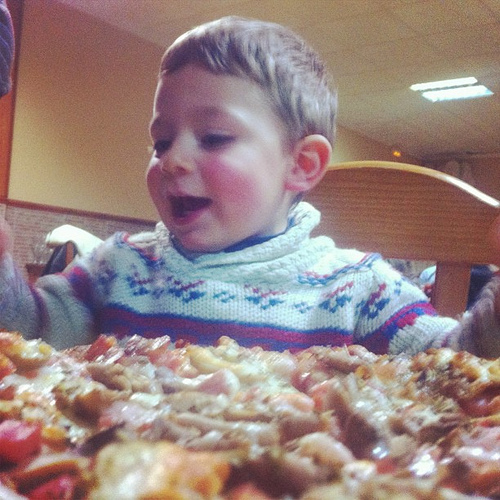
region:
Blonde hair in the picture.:
[162, 24, 352, 101]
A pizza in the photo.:
[143, 353, 480, 488]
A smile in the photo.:
[162, 180, 223, 230]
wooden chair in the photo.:
[322, 163, 472, 243]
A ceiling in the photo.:
[341, 4, 442, 54]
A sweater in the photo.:
[36, 232, 452, 347]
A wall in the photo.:
[25, 49, 116, 179]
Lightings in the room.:
[402, 70, 495, 109]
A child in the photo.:
[0, 17, 499, 357]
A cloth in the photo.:
[39, 222, 94, 261]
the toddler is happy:
[99, 57, 248, 241]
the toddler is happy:
[162, 152, 300, 262]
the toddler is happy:
[131, 97, 301, 302]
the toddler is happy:
[102, 97, 419, 356]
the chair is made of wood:
[350, 140, 420, 247]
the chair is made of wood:
[379, 158, 460, 300]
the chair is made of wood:
[364, 150, 487, 350]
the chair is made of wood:
[420, 151, 497, 313]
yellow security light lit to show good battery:
[389, 144, 403, 158]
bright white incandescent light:
[407, 75, 493, 103]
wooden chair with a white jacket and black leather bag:
[40, 223, 104, 279]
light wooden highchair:
[303, 159, 498, 317]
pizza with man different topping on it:
[0, 332, 499, 499]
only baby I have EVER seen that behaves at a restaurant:
[144, 14, 339, 251]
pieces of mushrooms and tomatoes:
[0, 417, 91, 498]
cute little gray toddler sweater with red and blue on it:
[0, 202, 499, 359]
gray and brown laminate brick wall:
[0, 196, 156, 286]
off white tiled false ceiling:
[56, 0, 498, 164]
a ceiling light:
[422, 83, 492, 103]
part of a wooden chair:
[307, 158, 498, 333]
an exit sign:
[390, 145, 405, 160]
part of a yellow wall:
[7, 3, 159, 219]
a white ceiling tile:
[325, 10, 410, 58]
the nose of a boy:
[159, 134, 200, 171]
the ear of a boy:
[289, 130, 329, 194]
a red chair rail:
[2, 200, 153, 240]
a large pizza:
[0, 328, 498, 498]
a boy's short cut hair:
[157, 19, 340, 211]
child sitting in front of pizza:
[56, 20, 456, 444]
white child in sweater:
[57, 10, 423, 355]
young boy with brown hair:
[109, 5, 381, 262]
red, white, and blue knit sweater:
[51, 202, 425, 388]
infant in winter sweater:
[49, 5, 476, 372]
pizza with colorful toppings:
[9, 317, 428, 498]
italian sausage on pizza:
[76, 350, 174, 410]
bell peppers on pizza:
[1, 412, 121, 494]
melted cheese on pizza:
[128, 374, 263, 461]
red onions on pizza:
[192, 358, 245, 406]